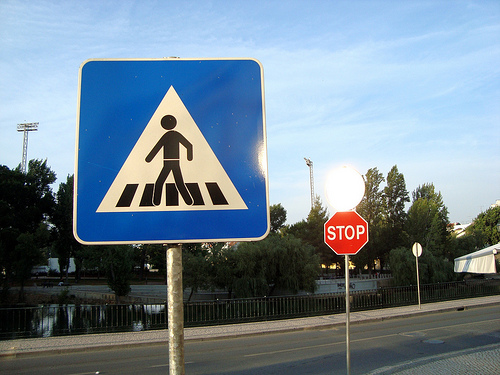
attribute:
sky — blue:
[277, 11, 498, 213]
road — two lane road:
[14, 295, 498, 369]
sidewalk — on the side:
[9, 287, 489, 354]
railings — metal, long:
[2, 278, 497, 338]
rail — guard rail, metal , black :
[0, 275, 497, 337]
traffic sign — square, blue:
[77, 60, 269, 242]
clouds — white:
[283, 36, 430, 146]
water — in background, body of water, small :
[39, 264, 331, 308]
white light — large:
[318, 162, 365, 210]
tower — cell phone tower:
[299, 155, 317, 212]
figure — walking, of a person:
[114, 113, 228, 207]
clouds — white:
[144, 17, 449, 59]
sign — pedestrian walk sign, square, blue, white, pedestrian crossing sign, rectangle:
[65, 50, 275, 250]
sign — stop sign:
[321, 211, 369, 256]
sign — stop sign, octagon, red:
[321, 207, 371, 255]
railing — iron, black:
[2, 275, 499, 336]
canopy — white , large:
[452, 240, 499, 275]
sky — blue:
[1, 0, 498, 222]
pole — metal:
[163, 245, 197, 373]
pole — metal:
[341, 252, 355, 372]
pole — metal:
[413, 257, 425, 311]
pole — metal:
[344, 255, 351, 374]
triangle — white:
[95, 83, 250, 214]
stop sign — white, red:
[321, 207, 371, 257]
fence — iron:
[160, 272, 430, 329]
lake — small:
[0, 297, 480, 342]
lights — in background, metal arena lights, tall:
[12, 117, 43, 168]